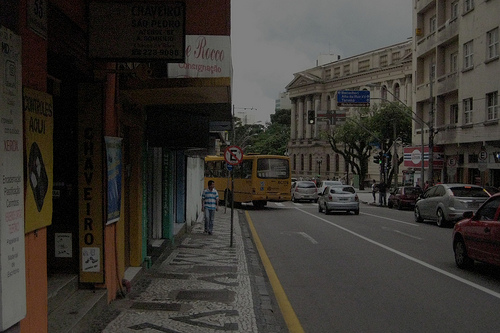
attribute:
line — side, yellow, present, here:
[250, 228, 311, 331]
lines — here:
[232, 209, 326, 327]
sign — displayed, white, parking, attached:
[214, 138, 281, 195]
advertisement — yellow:
[21, 91, 81, 211]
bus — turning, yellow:
[236, 136, 318, 254]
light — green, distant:
[300, 104, 323, 129]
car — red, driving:
[453, 191, 497, 276]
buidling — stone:
[412, 27, 488, 146]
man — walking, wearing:
[175, 169, 225, 222]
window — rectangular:
[455, 43, 472, 80]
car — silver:
[327, 179, 374, 223]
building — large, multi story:
[364, 20, 482, 149]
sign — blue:
[332, 88, 395, 119]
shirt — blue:
[186, 178, 245, 238]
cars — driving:
[273, 156, 465, 263]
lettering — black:
[119, 20, 204, 85]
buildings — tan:
[290, 46, 426, 150]